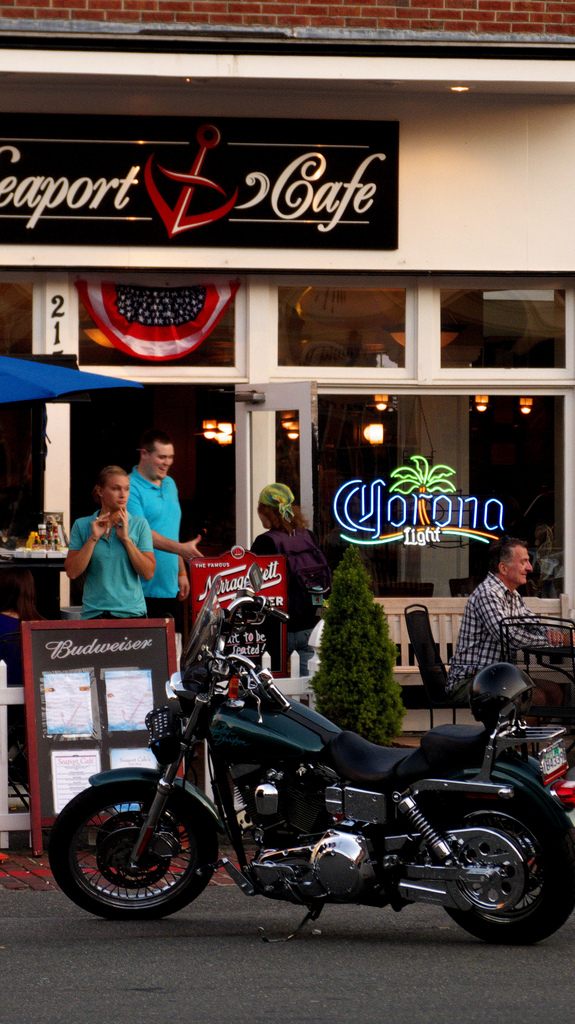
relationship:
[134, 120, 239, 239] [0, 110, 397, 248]
anchor on sign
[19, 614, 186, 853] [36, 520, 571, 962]
board behind motorcycle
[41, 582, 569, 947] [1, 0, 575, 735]
motorcycle parked front of a building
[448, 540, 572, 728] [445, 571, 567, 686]
man in shirt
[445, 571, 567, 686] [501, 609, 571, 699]
shirt sitting at table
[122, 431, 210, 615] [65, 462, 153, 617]
man and woman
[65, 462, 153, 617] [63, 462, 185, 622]
woman in blue shirts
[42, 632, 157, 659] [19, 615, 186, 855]
budweiser written on board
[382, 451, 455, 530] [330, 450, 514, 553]
tree on neon sign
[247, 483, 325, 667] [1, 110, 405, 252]
woman entering restaurant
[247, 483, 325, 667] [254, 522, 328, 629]
woman wearing purple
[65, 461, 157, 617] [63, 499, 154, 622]
woman wearing blue shirts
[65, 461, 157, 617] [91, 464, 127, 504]
woman has hair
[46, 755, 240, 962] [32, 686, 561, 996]
wheel on motorcycle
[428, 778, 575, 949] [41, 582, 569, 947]
wheel on back of motorcycle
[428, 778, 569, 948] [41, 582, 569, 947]
wheel on back of motorcycle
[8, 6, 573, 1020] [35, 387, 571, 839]
picture taken outdoors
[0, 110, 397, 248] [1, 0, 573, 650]
sign on building